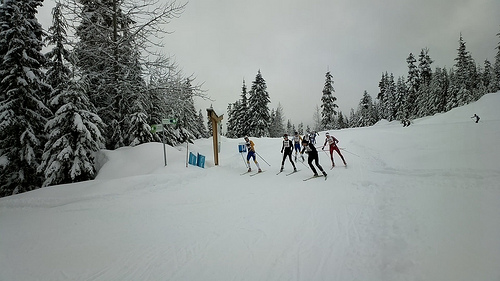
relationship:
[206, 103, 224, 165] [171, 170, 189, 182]
marker in snow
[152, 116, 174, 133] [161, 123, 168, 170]
sign on pole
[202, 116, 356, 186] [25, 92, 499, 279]
ground in snow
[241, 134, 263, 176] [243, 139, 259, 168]
skier in suit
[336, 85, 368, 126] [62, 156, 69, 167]
ground without leaves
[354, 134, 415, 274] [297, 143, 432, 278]
tracks on trail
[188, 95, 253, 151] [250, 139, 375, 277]
marker on slope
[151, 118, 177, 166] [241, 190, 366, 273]
sign placed ground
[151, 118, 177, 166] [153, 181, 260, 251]
sign surrounded snow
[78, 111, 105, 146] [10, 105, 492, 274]
branches heavy snow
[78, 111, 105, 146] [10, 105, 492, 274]
branches with snow